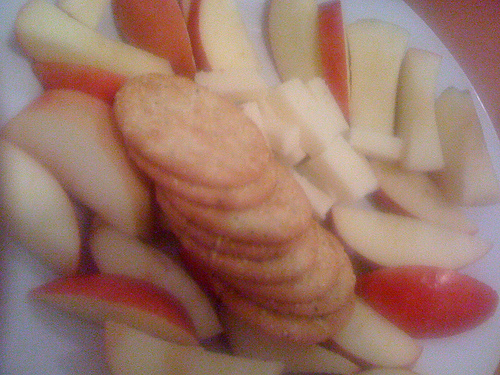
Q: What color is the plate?
A: White.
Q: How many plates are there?
A: One.